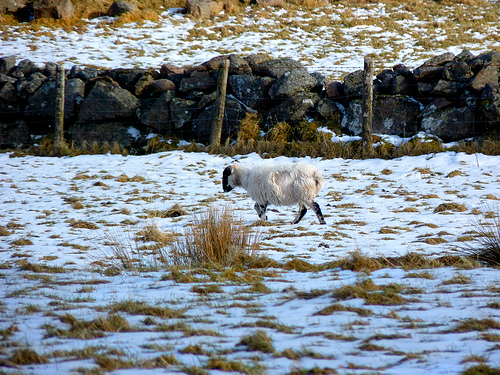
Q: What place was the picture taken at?
A: It was taken at the field.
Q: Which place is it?
A: It is a field.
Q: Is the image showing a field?
A: Yes, it is showing a field.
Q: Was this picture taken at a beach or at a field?
A: It was taken at a field.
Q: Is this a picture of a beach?
A: No, the picture is showing a field.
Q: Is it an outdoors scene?
A: Yes, it is outdoors.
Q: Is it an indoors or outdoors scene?
A: It is outdoors.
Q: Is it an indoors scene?
A: No, it is outdoors.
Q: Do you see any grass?
A: Yes, there is grass.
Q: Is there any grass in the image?
A: Yes, there is grass.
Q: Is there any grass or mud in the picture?
A: Yes, there is grass.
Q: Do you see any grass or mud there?
A: Yes, there is grass.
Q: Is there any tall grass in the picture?
A: Yes, there is tall grass.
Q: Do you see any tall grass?
A: Yes, there is tall grass.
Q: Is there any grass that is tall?
A: Yes, there is grass that is tall.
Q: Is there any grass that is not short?
A: Yes, there is tall grass.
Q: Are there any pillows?
A: No, there are no pillows.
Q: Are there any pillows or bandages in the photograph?
A: No, there are no pillows or bandages.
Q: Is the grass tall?
A: Yes, the grass is tall.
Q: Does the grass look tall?
A: Yes, the grass is tall.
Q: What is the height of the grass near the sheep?
A: The grass is tall.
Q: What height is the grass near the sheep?
A: The grass is tall.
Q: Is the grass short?
A: No, the grass is tall.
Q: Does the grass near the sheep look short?
A: No, the grass is tall.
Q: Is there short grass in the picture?
A: No, there is grass but it is tall.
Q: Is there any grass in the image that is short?
A: No, there is grass but it is tall.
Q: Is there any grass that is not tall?
A: No, there is grass but it is tall.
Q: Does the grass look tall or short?
A: The grass is tall.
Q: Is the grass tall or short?
A: The grass is tall.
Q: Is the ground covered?
A: Yes, the ground is covered.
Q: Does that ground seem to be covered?
A: Yes, the ground is covered.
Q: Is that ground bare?
A: No, the ground is covered.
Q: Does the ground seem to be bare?
A: No, the ground is covered.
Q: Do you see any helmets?
A: No, there are no helmets.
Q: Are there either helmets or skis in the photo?
A: No, there are no helmets or skis.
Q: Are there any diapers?
A: No, there are no diapers.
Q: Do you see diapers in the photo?
A: No, there are no diapers.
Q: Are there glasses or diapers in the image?
A: No, there are no diapers or glasses.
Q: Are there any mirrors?
A: No, there are no mirrors.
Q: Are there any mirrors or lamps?
A: No, there are no mirrors or lamps.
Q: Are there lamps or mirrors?
A: No, there are no mirrors or lamps.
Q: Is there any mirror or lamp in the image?
A: No, there are no mirrors or lamps.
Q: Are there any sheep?
A: Yes, there is a sheep.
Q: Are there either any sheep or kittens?
A: Yes, there is a sheep.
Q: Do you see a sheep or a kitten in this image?
A: Yes, there is a sheep.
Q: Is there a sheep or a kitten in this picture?
A: Yes, there is a sheep.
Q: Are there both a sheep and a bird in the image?
A: No, there is a sheep but no birds.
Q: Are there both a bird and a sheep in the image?
A: No, there is a sheep but no birds.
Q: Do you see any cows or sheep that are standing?
A: Yes, the sheep is standing.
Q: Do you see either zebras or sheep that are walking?
A: Yes, the sheep is walking.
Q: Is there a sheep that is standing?
A: Yes, there is a sheep that is standing.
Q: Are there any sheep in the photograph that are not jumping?
A: Yes, there is a sheep that is standing.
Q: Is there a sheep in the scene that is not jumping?
A: Yes, there is a sheep that is standing.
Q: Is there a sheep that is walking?
A: Yes, there is a sheep that is walking.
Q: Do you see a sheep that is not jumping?
A: Yes, there is a sheep that is walking .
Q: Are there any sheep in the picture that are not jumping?
A: Yes, there is a sheep that is walking.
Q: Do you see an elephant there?
A: No, there are no elephants.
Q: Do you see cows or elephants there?
A: No, there are no elephants or cows.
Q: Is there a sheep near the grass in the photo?
A: Yes, there is a sheep near the grass.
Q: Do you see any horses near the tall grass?
A: No, there is a sheep near the grass.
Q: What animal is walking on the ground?
A: The sheep is walking on the ground.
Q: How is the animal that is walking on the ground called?
A: The animal is a sheep.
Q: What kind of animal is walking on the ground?
A: The animal is a sheep.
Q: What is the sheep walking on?
A: The sheep is walking on the ground.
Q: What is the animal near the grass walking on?
A: The sheep is walking on the ground.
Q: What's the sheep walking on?
A: The sheep is walking on the ground.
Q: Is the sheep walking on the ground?
A: Yes, the sheep is walking on the ground.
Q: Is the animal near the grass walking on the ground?
A: Yes, the sheep is walking on the ground.